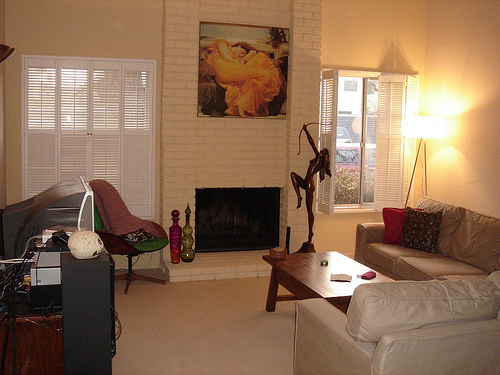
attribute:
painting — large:
[200, 21, 287, 119]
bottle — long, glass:
[167, 203, 182, 267]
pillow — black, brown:
[405, 207, 438, 254]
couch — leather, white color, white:
[293, 201, 500, 375]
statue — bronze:
[293, 121, 319, 252]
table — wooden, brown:
[267, 251, 399, 308]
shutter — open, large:
[320, 70, 334, 215]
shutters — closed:
[22, 54, 152, 219]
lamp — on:
[404, 116, 445, 212]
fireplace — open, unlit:
[196, 189, 279, 249]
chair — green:
[95, 203, 173, 294]